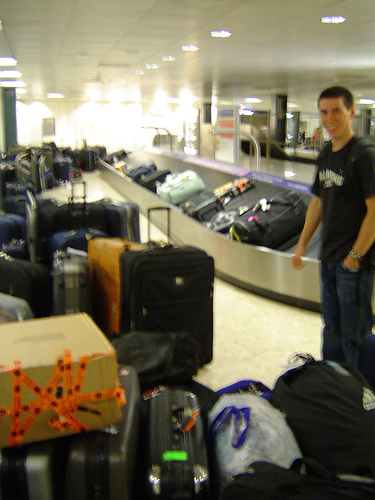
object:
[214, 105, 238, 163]
sign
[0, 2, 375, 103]
ceiling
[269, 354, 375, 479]
case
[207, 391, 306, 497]
luggage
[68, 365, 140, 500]
suitcase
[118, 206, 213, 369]
luggage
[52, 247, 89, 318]
luggage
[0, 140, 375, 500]
baggage claim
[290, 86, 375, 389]
man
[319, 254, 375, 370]
jeans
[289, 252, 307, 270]
hand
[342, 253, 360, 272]
hand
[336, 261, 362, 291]
pocket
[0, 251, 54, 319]
case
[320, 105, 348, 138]
smile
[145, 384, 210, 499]
black suitcase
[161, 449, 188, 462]
tag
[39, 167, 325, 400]
ground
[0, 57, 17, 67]
light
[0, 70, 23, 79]
light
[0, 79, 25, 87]
light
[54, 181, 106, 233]
suit case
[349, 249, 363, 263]
watch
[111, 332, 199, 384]
bag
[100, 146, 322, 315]
carousel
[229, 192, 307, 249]
luggage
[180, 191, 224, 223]
luggage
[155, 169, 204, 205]
luggage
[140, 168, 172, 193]
luggage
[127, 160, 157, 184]
luggage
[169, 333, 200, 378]
edge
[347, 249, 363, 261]
wrist